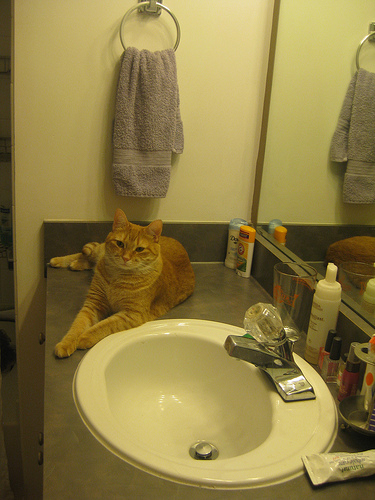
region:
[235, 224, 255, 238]
orange cap to deodorant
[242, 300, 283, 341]
white nozzle on sink faucet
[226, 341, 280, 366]
silver sink faucet for sink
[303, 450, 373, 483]
back end of toothpaste bottle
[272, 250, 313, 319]
small glass on counter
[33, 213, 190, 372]
cat laying on counter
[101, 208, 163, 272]
small orange head of cat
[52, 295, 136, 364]
orange and white paws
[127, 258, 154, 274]
white whiskers of cat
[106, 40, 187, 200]
purple hand towel by wall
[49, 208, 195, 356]
cat lying on counter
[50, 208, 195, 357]
the cat is orange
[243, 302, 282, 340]
clear plastic faucet handle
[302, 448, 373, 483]
a tube of toothpaste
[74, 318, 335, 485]
the sink is white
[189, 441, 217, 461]
the drain is silver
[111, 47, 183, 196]
purple towel hanging down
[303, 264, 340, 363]
a bottle of something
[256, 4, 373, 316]
mirror on the wall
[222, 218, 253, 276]
two bottles of deodorant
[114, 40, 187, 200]
lavender towel handing from towel ring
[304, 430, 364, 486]
tube of toothpaste on counter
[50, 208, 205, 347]
cat laying on counter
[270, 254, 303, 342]
glass on counter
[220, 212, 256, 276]
deodorant on counter in caorner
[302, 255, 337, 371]
hair product on counter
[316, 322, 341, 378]
two nail polishes on counter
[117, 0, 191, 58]
metal towel ring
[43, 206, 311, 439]
orange cat laying on vanity in bathroom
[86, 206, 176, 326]
orange cat looking at the camera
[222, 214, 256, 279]
deodorants are on the counter top in a corner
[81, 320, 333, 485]
round white sink in bathroom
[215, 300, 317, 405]
silver faucet for bathroom sink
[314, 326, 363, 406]
nail products behind the faucet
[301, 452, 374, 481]
part of tooth paste tube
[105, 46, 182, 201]
grey towel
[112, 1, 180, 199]
towel hanging from circular towel holder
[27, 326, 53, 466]
knobs on the cabinets below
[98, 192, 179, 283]
head of a cat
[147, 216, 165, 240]
ear of a cat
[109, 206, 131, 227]
ear of a cat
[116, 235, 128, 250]
eye of a cat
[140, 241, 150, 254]
eye of a cat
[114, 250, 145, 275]
mouth of a cat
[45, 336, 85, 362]
paw of a cat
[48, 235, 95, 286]
leg of a cat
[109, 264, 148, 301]
fur of a cat